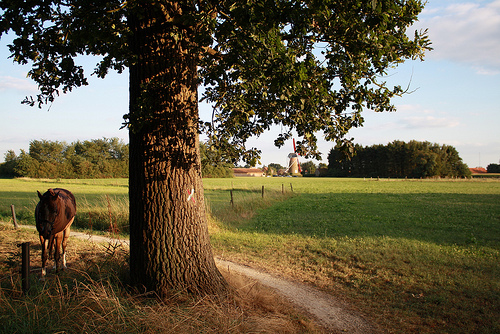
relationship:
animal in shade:
[34, 187, 76, 277] [11, 187, 483, 273]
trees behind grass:
[316, 136, 476, 179] [335, 176, 470, 201]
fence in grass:
[23, 180, 309, 243] [6, 176, 485, 328]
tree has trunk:
[0, 0, 437, 303] [129, 60, 230, 294]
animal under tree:
[32, 186, 72, 278] [0, 0, 437, 303]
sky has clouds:
[405, 7, 497, 154] [372, 103, 461, 148]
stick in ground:
[260, 185, 264, 198] [214, 184, 317, 231]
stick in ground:
[279, 182, 285, 193] [214, 184, 317, 231]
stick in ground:
[289, 182, 295, 193] [214, 184, 317, 231]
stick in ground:
[227, 191, 234, 208] [214, 184, 317, 231]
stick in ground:
[229, 179, 234, 189] [214, 184, 317, 231]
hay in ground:
[322, 232, 462, 312] [338, 199, 473, 311]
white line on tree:
[184, 185, 197, 205] [0, 0, 437, 303]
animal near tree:
[34, 187, 76, 277] [113, 15, 260, 307]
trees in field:
[322, 136, 476, 179] [6, 168, 499, 328]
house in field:
[228, 164, 267, 174] [6, 168, 499, 328]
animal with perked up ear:
[34, 187, 76, 277] [31, 187, 45, 202]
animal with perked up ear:
[34, 187, 76, 277] [48, 186, 65, 201]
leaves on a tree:
[0, 10, 438, 156] [0, 0, 437, 303]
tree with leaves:
[0, 0, 437, 303] [369, 89, 400, 116]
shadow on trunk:
[128, 53, 202, 181] [124, 2, 232, 300]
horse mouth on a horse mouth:
[35, 219, 55, 240] [35, 215, 55, 238]